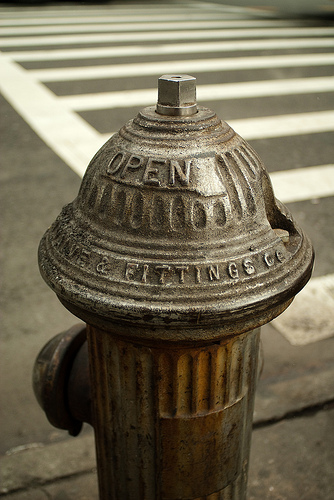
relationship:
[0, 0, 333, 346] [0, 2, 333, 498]
cross walk across paved street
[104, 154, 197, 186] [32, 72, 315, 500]
word on fire hydrant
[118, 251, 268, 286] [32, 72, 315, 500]
word on fire hydrant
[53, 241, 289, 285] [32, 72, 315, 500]
company made fire hydrant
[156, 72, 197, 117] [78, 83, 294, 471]
angle bolt on top of hydrant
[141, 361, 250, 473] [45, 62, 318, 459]
rust on bottom of hydrant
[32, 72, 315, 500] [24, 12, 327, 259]
fire hydrant near cross walk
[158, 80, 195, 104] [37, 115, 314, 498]
nut on top of hydrant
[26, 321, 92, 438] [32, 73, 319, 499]
nozzle of fire hydrant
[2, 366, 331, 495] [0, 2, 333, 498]
curb on paved street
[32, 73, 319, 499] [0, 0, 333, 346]
fire hydrant on cross walk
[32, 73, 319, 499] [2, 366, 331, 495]
fire hydrant next to curb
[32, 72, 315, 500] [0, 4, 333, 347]
fire hydrant near crosswalk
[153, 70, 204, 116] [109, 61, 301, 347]
angle bolt on hydrant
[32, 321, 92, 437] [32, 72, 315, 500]
nozzle from fire hydrant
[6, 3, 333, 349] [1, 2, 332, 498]
lines over paved street